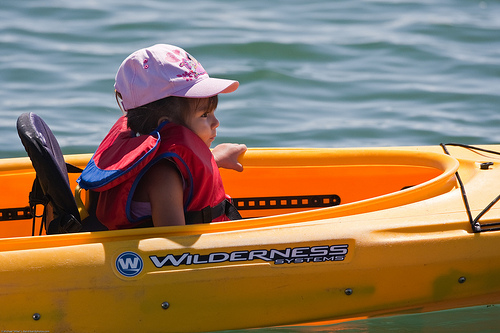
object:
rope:
[440, 141, 500, 233]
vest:
[77, 113, 241, 230]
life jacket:
[75, 114, 236, 227]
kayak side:
[212, 144, 444, 166]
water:
[1, 1, 497, 330]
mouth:
[207, 132, 217, 143]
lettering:
[148, 252, 190, 268]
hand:
[212, 141, 252, 173]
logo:
[112, 249, 145, 278]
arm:
[148, 167, 189, 227]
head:
[120, 63, 217, 156]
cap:
[112, 44, 240, 113]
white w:
[118, 257, 139, 269]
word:
[185, 254, 194, 264]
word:
[274, 258, 284, 265]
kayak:
[0, 111, 499, 330]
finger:
[237, 144, 247, 153]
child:
[79, 39, 249, 228]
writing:
[328, 243, 349, 256]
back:
[11, 109, 86, 223]